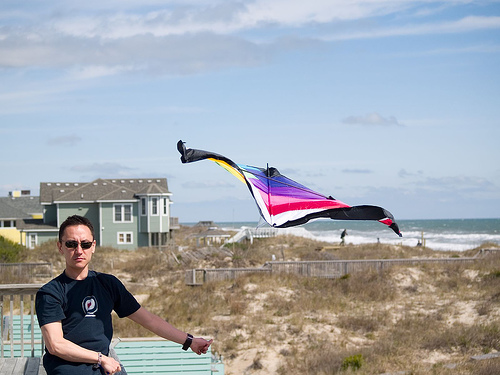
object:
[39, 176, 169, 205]
shingled roof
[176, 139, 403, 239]
kite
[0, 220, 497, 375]
ground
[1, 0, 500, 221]
sky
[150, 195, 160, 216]
window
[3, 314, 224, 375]
deck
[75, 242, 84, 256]
nose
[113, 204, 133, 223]
window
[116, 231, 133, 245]
windows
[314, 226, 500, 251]
waves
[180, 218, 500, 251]
ocean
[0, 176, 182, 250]
beachfront home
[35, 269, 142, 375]
shirt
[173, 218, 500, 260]
beach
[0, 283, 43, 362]
railing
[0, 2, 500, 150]
clouds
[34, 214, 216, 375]
man